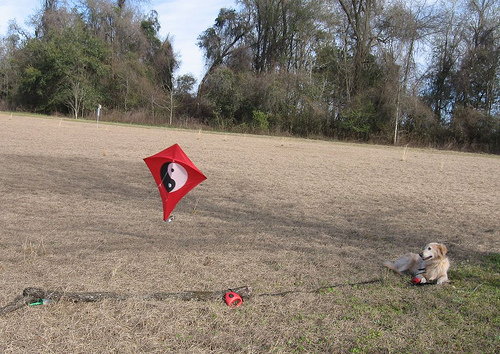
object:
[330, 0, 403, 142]
tree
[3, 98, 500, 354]
field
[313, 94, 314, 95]
leaves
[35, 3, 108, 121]
tree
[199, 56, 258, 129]
tree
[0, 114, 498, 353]
grass